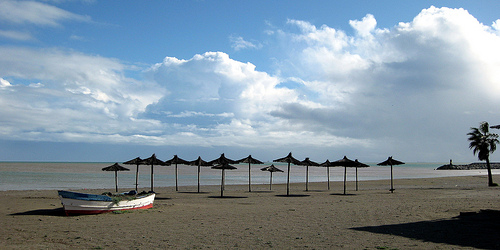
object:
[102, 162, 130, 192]
dark umbrellas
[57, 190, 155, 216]
boat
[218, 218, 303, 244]
footprints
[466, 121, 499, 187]
palm tree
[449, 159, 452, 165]
lighthouse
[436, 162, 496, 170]
flat land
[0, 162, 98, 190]
ocean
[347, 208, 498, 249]
shadow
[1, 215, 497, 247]
beach sand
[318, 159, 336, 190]
shorter umbrella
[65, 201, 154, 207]
stripes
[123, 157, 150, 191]
large umbrella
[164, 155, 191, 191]
large umbrella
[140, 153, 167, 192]
large umbrella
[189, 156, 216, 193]
large umbrella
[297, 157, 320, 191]
large umbrella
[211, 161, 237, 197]
large umbrella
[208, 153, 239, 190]
large umbrella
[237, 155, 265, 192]
large umbrella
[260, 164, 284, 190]
large umbrella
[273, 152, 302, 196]
large umbrella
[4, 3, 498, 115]
blue sky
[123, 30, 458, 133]
white clouds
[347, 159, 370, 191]
opened umbrella